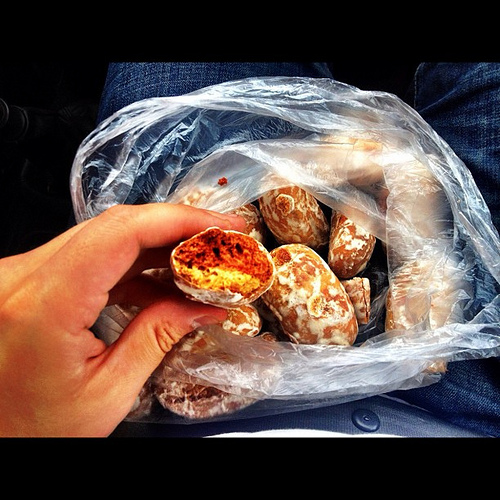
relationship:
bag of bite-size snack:
[63, 74, 499, 418] [168, 225, 278, 305]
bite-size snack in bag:
[168, 225, 278, 305] [211, 77, 456, 215]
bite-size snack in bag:
[264, 242, 359, 349] [129, 126, 476, 413]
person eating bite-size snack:
[6, 55, 496, 437] [168, 225, 278, 305]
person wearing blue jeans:
[6, 55, 496, 437] [46, 56, 498, 408]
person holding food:
[6, 55, 496, 437] [168, 222, 276, 303]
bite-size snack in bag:
[168, 225, 278, 305] [69, 74, 500, 426]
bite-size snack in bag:
[264, 242, 359, 349] [69, 74, 500, 426]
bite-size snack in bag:
[330, 197, 380, 273] [69, 74, 500, 426]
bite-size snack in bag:
[249, 171, 329, 241] [69, 74, 500, 426]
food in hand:
[177, 227, 378, 354] [0, 200, 250, 434]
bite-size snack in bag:
[264, 242, 359, 349] [63, 74, 499, 418]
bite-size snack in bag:
[264, 242, 359, 349] [279, 367, 364, 390]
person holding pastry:
[6, 55, 496, 437] [165, 230, 276, 310]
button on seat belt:
[348, 403, 385, 433] [192, 396, 496, 438]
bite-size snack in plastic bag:
[168, 225, 278, 305] [184, 119, 404, 216]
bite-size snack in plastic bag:
[264, 242, 359, 349] [184, 119, 404, 216]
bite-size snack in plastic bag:
[260, 180, 329, 240] [184, 119, 404, 216]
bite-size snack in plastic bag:
[330, 206, 376, 273] [184, 119, 404, 216]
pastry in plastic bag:
[343, 278, 375, 317] [184, 119, 404, 216]